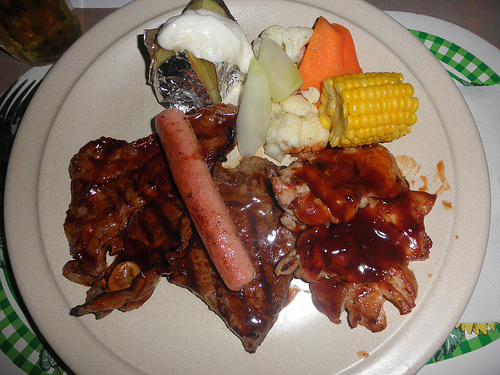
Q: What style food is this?
A: Barbecue.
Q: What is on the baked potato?
A: Sour cream.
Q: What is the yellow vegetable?
A: Corn.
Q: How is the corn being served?
A: On the cob.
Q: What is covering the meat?
A: Barbecue sauce.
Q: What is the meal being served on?
A: A paper plate.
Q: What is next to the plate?
A: A fork.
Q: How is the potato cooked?
A: Baked.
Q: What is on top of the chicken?
A: A hot dog.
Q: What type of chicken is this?
A: Barbecue.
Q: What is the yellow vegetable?
A: Corn.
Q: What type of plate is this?
A: Paper.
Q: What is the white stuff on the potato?
A: Sour cream.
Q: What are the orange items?
A: Carrots.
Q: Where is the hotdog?
A: On the plate.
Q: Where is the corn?
A: On the plate.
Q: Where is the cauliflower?
A: On the plate.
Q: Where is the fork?
A: To the left of the plate.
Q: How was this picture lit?
A: Indoor lighting.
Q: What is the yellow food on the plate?
A: Cord.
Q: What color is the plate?
A: White.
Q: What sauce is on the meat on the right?
A: Barbecue.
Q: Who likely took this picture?
A: The person about to eat the food.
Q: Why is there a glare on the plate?
A: From the light overhead.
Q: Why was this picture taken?
A: To show off the meal.